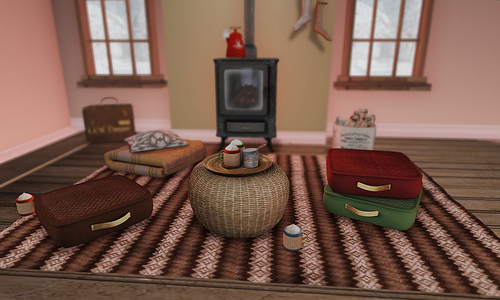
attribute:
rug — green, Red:
[313, 220, 437, 298]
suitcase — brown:
[30, 171, 155, 245]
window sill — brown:
[76, 71, 175, 92]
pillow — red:
[319, 143, 424, 203]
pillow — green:
[317, 176, 424, 235]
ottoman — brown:
[185, 150, 291, 238]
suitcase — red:
[327, 142, 423, 198]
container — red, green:
[324, 184, 423, 229]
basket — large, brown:
[185, 140, 287, 234]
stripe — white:
[132, 197, 218, 281]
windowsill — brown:
[335, 70, 432, 85]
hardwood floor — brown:
[3, 138, 498, 239]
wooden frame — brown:
[324, 14, 442, 97]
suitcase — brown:
[33, 173, 154, 240]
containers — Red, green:
[290, 126, 456, 249]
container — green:
[318, 184, 427, 234]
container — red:
[320, 148, 427, 198]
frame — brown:
[72, 2, 169, 89]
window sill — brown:
[334, 78, 434, 92]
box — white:
[331, 125, 378, 152]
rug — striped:
[0, 151, 499, 293]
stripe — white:
[0, 227, 42, 269]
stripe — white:
[32, 246, 82, 272]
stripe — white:
[84, 169, 188, 273]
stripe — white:
[187, 235, 223, 277]